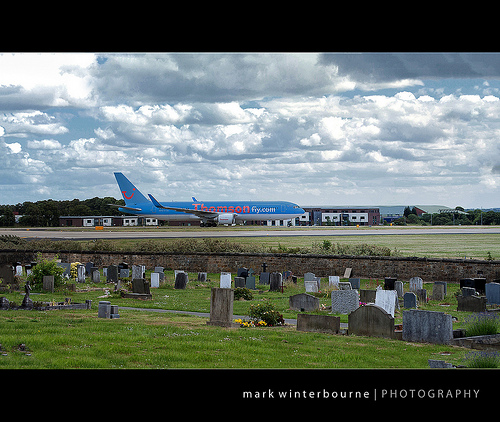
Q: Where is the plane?
A: Above the runway.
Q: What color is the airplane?
A: Blue and white.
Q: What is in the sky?
A: White puffy clouds.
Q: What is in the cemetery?
A: Headstones.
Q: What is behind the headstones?
A: A wall.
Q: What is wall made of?
A: Stones.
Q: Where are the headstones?
A: A cemetary.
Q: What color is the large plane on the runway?
A: Blue.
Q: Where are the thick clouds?
A: In the sky.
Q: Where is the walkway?
A: In the cemetery.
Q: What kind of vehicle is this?
A: Airplane.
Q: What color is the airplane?
A: Blue, white and red.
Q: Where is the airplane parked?
A: Concrete runway.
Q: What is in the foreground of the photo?
A: Cemetery.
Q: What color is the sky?
A: Blue and white.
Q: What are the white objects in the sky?
A: Clouds.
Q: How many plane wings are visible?
A: One.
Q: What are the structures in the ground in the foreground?
A: Headstones.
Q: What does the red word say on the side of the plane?
A: Thomson.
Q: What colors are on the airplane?
A: Blue and white.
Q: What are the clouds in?
A: Cluster.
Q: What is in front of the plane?
A: Graveyard.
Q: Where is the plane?
A: Run way.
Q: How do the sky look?
A: Cloudy.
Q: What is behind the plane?
A: Buildings.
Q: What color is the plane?
A: Blue.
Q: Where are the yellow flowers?
A: Graveyard.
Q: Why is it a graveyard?
A: Headstones.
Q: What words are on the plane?
A: thomsonfly.com.